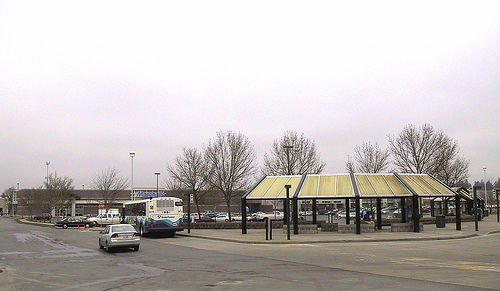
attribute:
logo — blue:
[160, 209, 172, 221]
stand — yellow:
[234, 165, 476, 199]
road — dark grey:
[0, 226, 494, 283]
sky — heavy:
[0, 3, 499, 188]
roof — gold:
[241, 172, 457, 203]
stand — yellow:
[247, 186, 298, 250]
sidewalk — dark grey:
[132, 243, 409, 290]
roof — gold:
[249, 174, 454, 202]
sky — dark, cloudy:
[161, 17, 476, 137]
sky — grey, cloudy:
[4, 12, 498, 202]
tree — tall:
[165, 146, 208, 226]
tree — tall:
[202, 127, 256, 222]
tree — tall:
[254, 132, 320, 174]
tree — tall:
[344, 138, 394, 173]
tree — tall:
[387, 121, 464, 183]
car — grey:
[91, 210, 146, 260]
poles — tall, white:
[69, 179, 217, 266]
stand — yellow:
[263, 170, 398, 191]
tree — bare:
[157, 144, 220, 234]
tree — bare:
[189, 111, 259, 232]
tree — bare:
[254, 128, 326, 178]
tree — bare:
[336, 136, 393, 179]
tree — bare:
[386, 108, 461, 198]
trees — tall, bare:
[173, 130, 482, 243]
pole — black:
[235, 197, 253, 236]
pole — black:
[350, 192, 365, 235]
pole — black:
[370, 192, 385, 229]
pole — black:
[407, 189, 423, 235]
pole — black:
[449, 189, 467, 232]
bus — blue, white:
[119, 197, 186, 235]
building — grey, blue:
[62, 172, 238, 226]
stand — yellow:
[259, 177, 449, 197]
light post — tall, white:
[125, 149, 142, 210]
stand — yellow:
[243, 170, 457, 200]